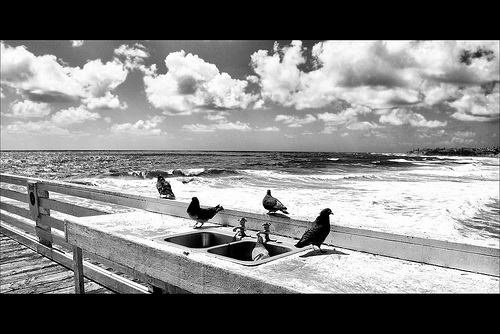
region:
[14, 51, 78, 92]
white clouds against blue sky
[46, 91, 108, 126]
white clouds against blue sky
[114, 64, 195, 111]
white clouds against blue sky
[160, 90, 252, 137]
white clouds against blue sky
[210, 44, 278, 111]
white clouds against blue sky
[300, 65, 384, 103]
white clouds against blue sky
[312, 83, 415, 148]
white clouds against blue sky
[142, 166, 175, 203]
dark bird on table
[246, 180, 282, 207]
dark bird on table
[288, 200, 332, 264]
dark bird on table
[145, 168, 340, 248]
several birds outside by water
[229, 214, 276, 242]
faucet to double sink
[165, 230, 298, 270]
double sink near birds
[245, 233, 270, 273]
bird resting in one of sinks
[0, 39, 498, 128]
clouds in the sky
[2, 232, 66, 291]
deck outside by water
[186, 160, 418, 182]
wave in the water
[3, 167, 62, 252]
fence area by deck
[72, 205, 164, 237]
counter area near sink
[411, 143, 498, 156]
buildings and green space behind water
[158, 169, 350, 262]
Pigeons in a black and white photo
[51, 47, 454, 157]
Many clouds in the sky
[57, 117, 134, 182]
The water is very choppy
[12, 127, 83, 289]
A boardwalk near the sea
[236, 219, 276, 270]
A pigeon in a sink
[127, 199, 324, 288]
A sink in a piece of wood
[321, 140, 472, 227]
The water ir rough and choppy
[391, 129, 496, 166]
A rocky area near the sea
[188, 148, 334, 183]
Waves coming in from the sea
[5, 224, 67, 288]
A walkway made of wood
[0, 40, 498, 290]
Ocean scene in black and white.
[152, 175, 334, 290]
Five birds by an outdoor sink.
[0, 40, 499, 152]
Fluffy clouds spread across the sky.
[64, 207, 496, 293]
Outdoor table with metal sink.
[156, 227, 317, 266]
Bird is in the right half of the sink.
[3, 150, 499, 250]
Ocean water is choppy and foamy.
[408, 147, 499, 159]
A piece of land jutting out into the surf.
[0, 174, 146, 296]
Railings on wooden walkway are horizontal.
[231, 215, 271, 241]
Two faucets are next to each other.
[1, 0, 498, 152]
A black line covers part of the sky.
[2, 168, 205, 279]
The wooden post fence.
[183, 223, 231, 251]
The sink on the left.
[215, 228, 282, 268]
The sink on the right.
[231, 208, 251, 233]
The faucet handle on the left.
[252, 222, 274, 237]
The faucet handle on the right.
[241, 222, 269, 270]
The bird in the sink on the right.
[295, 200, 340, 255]
The black bird on the right.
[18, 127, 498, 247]
The water in front of where the birds are located.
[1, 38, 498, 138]
The white clouds in the sky.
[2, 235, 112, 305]
The wooden boardwalk to the left of the wooden post fence.